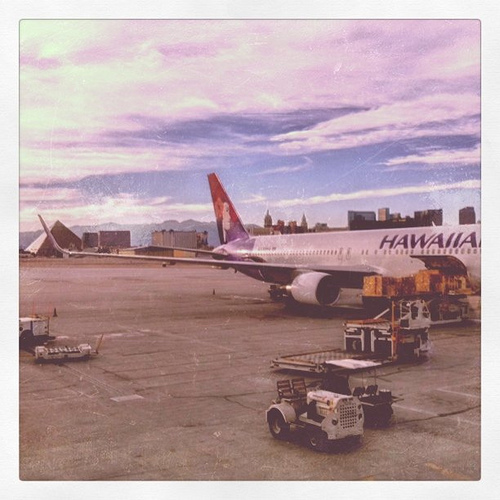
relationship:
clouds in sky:
[19, 18, 479, 228] [19, 19, 482, 229]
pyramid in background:
[26, 220, 85, 256] [26, 220, 83, 258]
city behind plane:
[26, 206, 480, 254] [37, 173, 481, 307]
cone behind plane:
[211, 288, 218, 295] [37, 173, 481, 307]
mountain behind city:
[18, 220, 266, 249] [26, 206, 480, 254]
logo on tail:
[213, 195, 249, 244] [206, 170, 249, 242]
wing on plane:
[37, 214, 379, 276] [37, 173, 481, 307]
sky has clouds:
[19, 19, 482, 229] [19, 18, 479, 228]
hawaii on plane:
[379, 233, 461, 249] [37, 173, 481, 307]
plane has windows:
[37, 173, 481, 307] [233, 245, 482, 261]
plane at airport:
[37, 173, 481, 307] [18, 21, 480, 483]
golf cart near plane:
[323, 358, 403, 428] [37, 173, 481, 307]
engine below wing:
[285, 272, 341, 307] [37, 214, 379, 276]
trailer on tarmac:
[35, 334, 108, 366] [20, 254, 480, 482]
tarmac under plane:
[20, 254, 480, 482] [37, 173, 481, 307]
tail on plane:
[206, 170, 249, 242] [37, 173, 481, 307]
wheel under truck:
[267, 407, 290, 439] [266, 380, 366, 450]